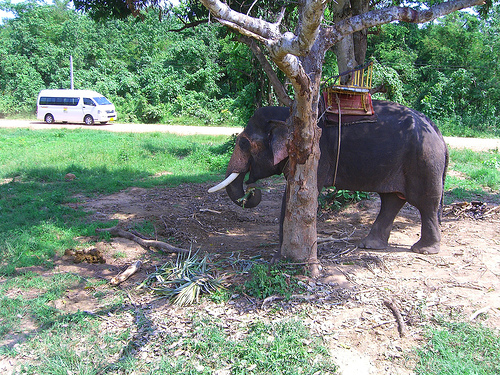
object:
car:
[35, 86, 119, 127]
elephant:
[208, 98, 451, 257]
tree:
[70, 2, 486, 262]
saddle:
[319, 61, 376, 119]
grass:
[3, 131, 131, 174]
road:
[1, 117, 500, 152]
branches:
[111, 229, 195, 253]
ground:
[77, 183, 498, 372]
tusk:
[204, 168, 240, 196]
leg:
[406, 175, 444, 254]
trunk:
[275, 57, 322, 262]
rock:
[231, 292, 241, 300]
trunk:
[222, 170, 263, 211]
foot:
[410, 239, 442, 258]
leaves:
[258, 277, 263, 281]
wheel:
[84, 114, 94, 125]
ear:
[269, 115, 292, 166]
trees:
[0, 56, 44, 116]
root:
[94, 223, 199, 284]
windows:
[83, 97, 97, 107]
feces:
[88, 252, 96, 257]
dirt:
[58, 200, 499, 369]